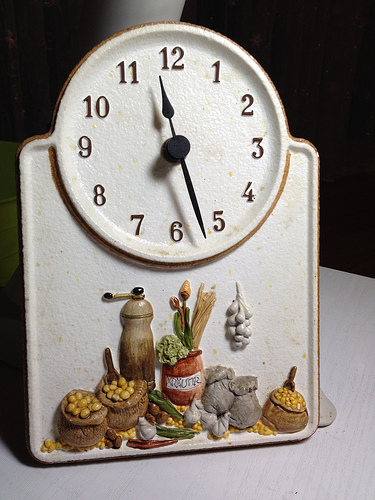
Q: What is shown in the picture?
A: A clock.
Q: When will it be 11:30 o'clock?
A: In about 3 minutes.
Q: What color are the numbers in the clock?
A: Black.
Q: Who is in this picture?
A: No human.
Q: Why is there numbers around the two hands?
A: It's a clock.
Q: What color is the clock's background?
A: White.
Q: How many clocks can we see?
A: One.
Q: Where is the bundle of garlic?
A: Below the clock but in the same frame.